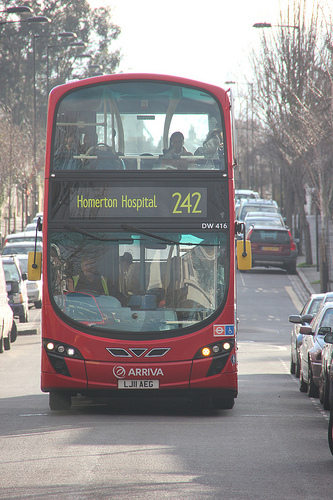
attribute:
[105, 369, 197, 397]
plate — short, wide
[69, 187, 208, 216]
sign — electronic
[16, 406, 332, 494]
picture — from street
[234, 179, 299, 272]
vehicles — parked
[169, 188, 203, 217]
242 — number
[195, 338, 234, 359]
nightlights — low-light conditions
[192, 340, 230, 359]
lights — on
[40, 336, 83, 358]
lights — on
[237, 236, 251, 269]
mirror — side, yellow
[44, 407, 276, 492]
asphalt — for driving safely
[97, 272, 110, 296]
vest — yellow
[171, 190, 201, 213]
242 — number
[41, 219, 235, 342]
windshield — very large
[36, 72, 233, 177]
level — upper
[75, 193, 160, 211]
letters — green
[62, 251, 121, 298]
passenger — male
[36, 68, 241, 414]
bus — double decker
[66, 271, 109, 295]
vest — yellow